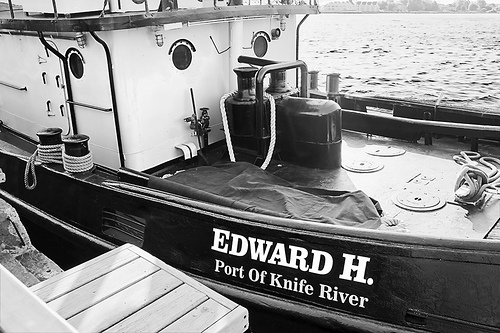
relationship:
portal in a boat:
[167, 40, 197, 68] [0, 6, 499, 326]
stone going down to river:
[30, 237, 252, 332] [297, 11, 499, 105]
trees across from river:
[375, 1, 497, 13] [297, 11, 499, 105]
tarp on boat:
[137, 151, 383, 228] [0, 6, 499, 326]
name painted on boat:
[211, 224, 380, 314] [0, 6, 499, 326]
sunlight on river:
[302, 16, 443, 97] [297, 11, 499, 105]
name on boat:
[211, 224, 380, 314] [0, 6, 499, 326]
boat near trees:
[323, 3, 384, 17] [375, 1, 497, 13]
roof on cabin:
[7, 7, 311, 26] [6, 18, 310, 166]